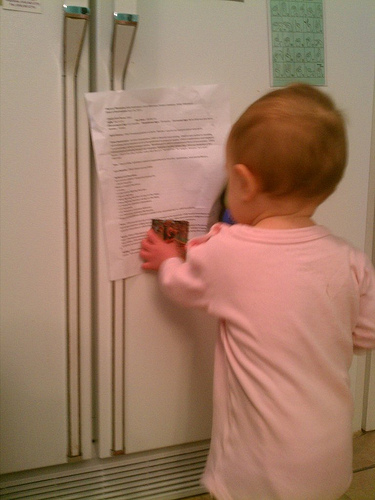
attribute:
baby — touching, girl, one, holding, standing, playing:
[211, 103, 345, 500]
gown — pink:
[199, 265, 341, 481]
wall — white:
[14, 116, 53, 261]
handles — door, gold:
[46, 35, 98, 134]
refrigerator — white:
[0, 181, 201, 430]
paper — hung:
[115, 104, 217, 196]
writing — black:
[101, 118, 174, 158]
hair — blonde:
[252, 85, 325, 184]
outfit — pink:
[197, 216, 339, 446]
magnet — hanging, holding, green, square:
[160, 141, 207, 244]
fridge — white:
[83, 32, 207, 470]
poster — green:
[241, 17, 343, 96]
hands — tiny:
[135, 231, 189, 275]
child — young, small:
[168, 122, 313, 473]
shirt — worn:
[184, 221, 323, 429]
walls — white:
[25, 53, 98, 200]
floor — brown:
[331, 433, 374, 474]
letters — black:
[126, 144, 181, 189]